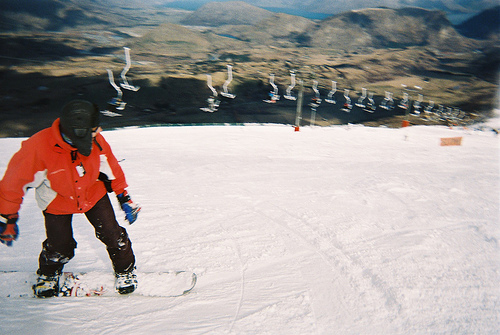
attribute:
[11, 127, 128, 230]
coat — red and white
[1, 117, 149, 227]
parka — orange and white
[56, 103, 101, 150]
hat — black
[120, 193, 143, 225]
glove — blue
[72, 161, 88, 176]
pass — ski, lift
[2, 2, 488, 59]
mountains — distant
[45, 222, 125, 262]
snow pants — brown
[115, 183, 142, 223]
gloves — winter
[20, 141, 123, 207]
jacket — orange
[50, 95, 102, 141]
helmet — black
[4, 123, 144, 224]
jacket — red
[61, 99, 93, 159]
head covering — black